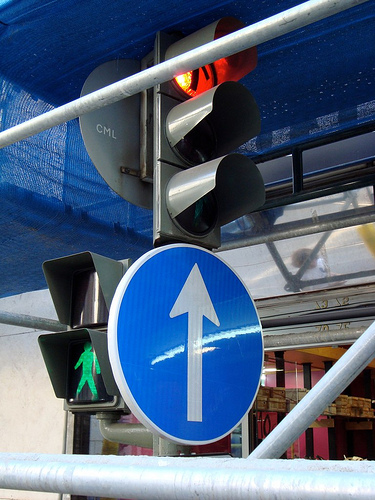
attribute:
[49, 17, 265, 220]
sign —  circular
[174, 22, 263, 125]
red light —  red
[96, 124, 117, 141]
cml —  in white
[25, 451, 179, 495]
metal pole — iron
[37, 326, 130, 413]
light — white 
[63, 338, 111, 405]
light — green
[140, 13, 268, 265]
lights —  in grey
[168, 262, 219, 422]
arrow —  white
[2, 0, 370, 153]
pole — iron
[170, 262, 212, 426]
arrow — white 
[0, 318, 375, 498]
pole —  grey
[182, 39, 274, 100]
light — red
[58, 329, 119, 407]
crossing ligth —  green,  for crossing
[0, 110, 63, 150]
bar — grey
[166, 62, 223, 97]
light — red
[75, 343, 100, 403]
green man —  green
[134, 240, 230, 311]
sign — blue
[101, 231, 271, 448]
sign —  blue and white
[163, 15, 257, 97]
light — red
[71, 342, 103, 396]
man —  green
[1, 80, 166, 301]
canopy —  blue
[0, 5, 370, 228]
tarp — blue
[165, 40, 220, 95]
light — red